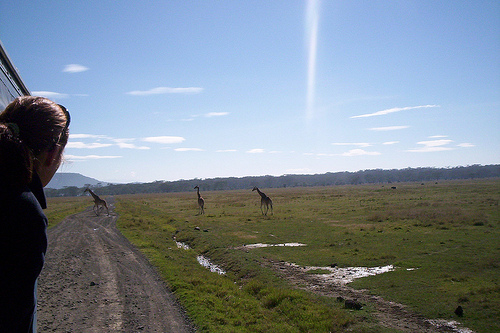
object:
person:
[0, 95, 72, 333]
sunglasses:
[48, 103, 72, 153]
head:
[1, 95, 71, 189]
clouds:
[124, 84, 203, 96]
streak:
[303, 0, 322, 129]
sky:
[0, 0, 500, 189]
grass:
[113, 177, 500, 333]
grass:
[35, 195, 105, 228]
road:
[31, 197, 194, 333]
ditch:
[173, 233, 310, 332]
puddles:
[234, 241, 309, 248]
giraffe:
[84, 186, 110, 217]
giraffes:
[194, 184, 206, 214]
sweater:
[0, 173, 51, 333]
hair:
[0, 95, 72, 201]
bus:
[0, 40, 33, 119]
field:
[113, 176, 500, 333]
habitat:
[33, 162, 500, 333]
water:
[171, 235, 226, 274]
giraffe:
[251, 186, 275, 217]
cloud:
[350, 103, 441, 120]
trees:
[480, 163, 492, 179]